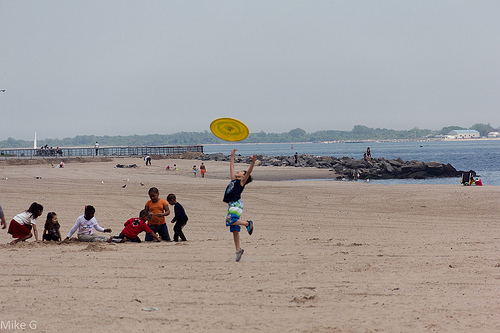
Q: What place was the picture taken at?
A: It was taken at the beach.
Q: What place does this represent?
A: It represents the beach.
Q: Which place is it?
A: It is a beach.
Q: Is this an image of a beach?
A: Yes, it is showing a beach.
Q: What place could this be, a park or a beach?
A: It is a beach.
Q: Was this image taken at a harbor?
A: No, the picture was taken in a beach.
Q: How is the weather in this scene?
A: It is overcast.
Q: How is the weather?
A: It is overcast.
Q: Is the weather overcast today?
A: Yes, it is overcast.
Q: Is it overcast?
A: Yes, it is overcast.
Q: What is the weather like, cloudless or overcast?
A: It is overcast.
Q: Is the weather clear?
A: No, it is overcast.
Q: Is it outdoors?
A: Yes, it is outdoors.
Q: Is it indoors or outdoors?
A: It is outdoors.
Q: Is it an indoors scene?
A: No, it is outdoors.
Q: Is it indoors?
A: No, it is outdoors.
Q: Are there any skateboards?
A: No, there are no skateboards.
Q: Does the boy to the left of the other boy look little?
A: Yes, the boy is little.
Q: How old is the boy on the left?
A: The boy is little.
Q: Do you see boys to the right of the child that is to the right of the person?
A: Yes, there is a boy to the right of the child.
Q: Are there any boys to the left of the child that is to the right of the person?
A: No, the boy is to the right of the child.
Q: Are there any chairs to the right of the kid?
A: No, there is a boy to the right of the kid.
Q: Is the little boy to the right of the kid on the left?
A: Yes, the boy is to the right of the kid.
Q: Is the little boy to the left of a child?
A: No, the boy is to the right of a child.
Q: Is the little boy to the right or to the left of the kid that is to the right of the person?
A: The boy is to the right of the kid.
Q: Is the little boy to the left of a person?
A: Yes, the boy is to the left of a person.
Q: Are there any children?
A: Yes, there is a child.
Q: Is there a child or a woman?
A: Yes, there is a child.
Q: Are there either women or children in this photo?
A: Yes, there is a child.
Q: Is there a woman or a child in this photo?
A: Yes, there is a child.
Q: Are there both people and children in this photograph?
A: Yes, there are both a child and a person.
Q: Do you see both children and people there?
A: Yes, there are both a child and a person.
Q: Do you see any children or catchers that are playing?
A: Yes, the child is playing.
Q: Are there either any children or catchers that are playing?
A: Yes, the child is playing.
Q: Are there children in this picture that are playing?
A: Yes, there is a child that is playing.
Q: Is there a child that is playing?
A: Yes, there is a child that is playing.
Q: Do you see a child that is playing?
A: Yes, there is a child that is playing.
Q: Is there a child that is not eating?
A: Yes, there is a child that is playing.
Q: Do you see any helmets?
A: No, there are no helmets.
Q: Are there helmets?
A: No, there are no helmets.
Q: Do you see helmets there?
A: No, there are no helmets.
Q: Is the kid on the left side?
A: Yes, the kid is on the left of the image.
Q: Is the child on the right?
A: No, the child is on the left of the image.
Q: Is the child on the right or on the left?
A: The child is on the left of the image.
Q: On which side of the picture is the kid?
A: The kid is on the left of the image.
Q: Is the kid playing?
A: Yes, the kid is playing.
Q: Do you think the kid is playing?
A: Yes, the kid is playing.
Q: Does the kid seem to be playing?
A: Yes, the kid is playing.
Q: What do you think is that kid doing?
A: The kid is playing.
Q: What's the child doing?
A: The kid is playing.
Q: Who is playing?
A: The child is playing.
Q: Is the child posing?
A: No, the child is playing.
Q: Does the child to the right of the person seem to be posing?
A: No, the child is playing.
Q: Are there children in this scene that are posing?
A: No, there is a child but he is playing.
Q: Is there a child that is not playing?
A: No, there is a child but he is playing.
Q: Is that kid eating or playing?
A: The kid is playing.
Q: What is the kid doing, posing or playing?
A: The kid is playing.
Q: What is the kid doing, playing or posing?
A: The kid is playing.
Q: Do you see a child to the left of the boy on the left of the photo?
A: Yes, there is a child to the left of the boy.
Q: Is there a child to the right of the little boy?
A: No, the child is to the left of the boy.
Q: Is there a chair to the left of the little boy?
A: No, there is a child to the left of the boy.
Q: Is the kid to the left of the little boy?
A: Yes, the kid is to the left of the boy.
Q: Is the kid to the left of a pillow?
A: No, the kid is to the left of the boy.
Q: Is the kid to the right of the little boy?
A: No, the kid is to the left of the boy.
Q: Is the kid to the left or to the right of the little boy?
A: The kid is to the left of the boy.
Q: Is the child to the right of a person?
A: No, the child is to the left of a person.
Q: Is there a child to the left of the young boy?
A: Yes, there is a child to the left of the boy.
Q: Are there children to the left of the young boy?
A: Yes, there is a child to the left of the boy.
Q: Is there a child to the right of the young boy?
A: No, the child is to the left of the boy.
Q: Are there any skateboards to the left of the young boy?
A: No, there is a child to the left of the boy.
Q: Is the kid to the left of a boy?
A: Yes, the kid is to the left of a boy.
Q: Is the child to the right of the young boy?
A: No, the child is to the left of the boy.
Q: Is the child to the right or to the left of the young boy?
A: The child is to the left of the boy.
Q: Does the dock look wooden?
A: Yes, the dock is wooden.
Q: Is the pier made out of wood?
A: Yes, the pier is made of wood.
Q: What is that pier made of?
A: The pier is made of wood.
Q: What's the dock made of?
A: The pier is made of wood.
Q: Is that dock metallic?
A: No, the dock is wooden.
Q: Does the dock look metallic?
A: No, the dock is wooden.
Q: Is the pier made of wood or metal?
A: The pier is made of wood.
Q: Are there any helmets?
A: No, there are no helmets.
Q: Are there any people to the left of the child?
A: Yes, there is a person to the left of the child.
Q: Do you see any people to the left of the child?
A: Yes, there is a person to the left of the child.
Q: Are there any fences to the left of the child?
A: No, there is a person to the left of the child.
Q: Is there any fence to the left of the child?
A: No, there is a person to the left of the child.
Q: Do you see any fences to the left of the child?
A: No, there is a person to the left of the child.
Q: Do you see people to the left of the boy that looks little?
A: Yes, there is a person to the left of the boy.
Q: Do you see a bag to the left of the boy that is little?
A: No, there is a person to the left of the boy.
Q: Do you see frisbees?
A: Yes, there is a frisbee.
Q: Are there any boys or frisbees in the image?
A: Yes, there is a frisbee.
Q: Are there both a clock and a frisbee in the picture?
A: No, there is a frisbee but no clocks.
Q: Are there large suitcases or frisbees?
A: Yes, there is a large frisbee.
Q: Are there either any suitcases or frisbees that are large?
A: Yes, the frisbee is large.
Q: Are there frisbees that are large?
A: Yes, there is a large frisbee.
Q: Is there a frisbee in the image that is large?
A: Yes, there is a frisbee that is large.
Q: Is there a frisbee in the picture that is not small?
A: Yes, there is a large frisbee.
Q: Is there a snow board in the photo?
A: No, there are no snowboards.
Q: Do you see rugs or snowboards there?
A: No, there are no snowboards or rugs.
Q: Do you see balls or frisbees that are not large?
A: No, there is a frisbee but it is large.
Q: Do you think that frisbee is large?
A: Yes, the frisbee is large.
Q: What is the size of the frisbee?
A: The frisbee is large.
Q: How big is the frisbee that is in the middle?
A: The frisbee is large.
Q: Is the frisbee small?
A: No, the frisbee is large.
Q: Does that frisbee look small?
A: No, the frisbee is large.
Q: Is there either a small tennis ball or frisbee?
A: No, there is a frisbee but it is large.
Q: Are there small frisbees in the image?
A: No, there is a frisbee but it is large.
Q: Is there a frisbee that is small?
A: No, there is a frisbee but it is large.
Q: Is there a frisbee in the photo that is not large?
A: No, there is a frisbee but it is large.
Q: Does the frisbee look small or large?
A: The frisbee is large.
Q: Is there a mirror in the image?
A: No, there are no mirrors.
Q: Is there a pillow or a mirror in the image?
A: No, there are no mirrors or pillows.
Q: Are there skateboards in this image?
A: No, there are no skateboards.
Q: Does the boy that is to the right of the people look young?
A: Yes, the boy is young.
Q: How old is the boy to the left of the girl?
A: The boy is young.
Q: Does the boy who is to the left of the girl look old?
A: No, the boy is young.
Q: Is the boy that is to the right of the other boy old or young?
A: The boy is young.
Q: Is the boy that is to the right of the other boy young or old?
A: The boy is young.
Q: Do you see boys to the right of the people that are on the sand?
A: Yes, there is a boy to the right of the people.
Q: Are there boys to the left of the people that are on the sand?
A: No, the boy is to the right of the people.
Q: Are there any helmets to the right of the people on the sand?
A: No, there is a boy to the right of the people.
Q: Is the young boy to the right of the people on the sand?
A: Yes, the boy is to the right of the people.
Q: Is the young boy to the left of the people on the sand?
A: No, the boy is to the right of the people.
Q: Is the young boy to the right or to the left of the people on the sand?
A: The boy is to the right of the people.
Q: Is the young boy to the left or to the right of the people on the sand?
A: The boy is to the right of the people.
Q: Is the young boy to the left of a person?
A: Yes, the boy is to the left of a person.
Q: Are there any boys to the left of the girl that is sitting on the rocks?
A: Yes, there is a boy to the left of the girl.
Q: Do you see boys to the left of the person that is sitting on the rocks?
A: Yes, there is a boy to the left of the girl.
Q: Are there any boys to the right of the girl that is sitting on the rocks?
A: No, the boy is to the left of the girl.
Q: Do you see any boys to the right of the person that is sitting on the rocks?
A: No, the boy is to the left of the girl.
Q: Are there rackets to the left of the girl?
A: No, there is a boy to the left of the girl.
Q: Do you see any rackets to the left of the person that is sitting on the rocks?
A: No, there is a boy to the left of the girl.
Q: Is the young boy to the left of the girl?
A: Yes, the boy is to the left of the girl.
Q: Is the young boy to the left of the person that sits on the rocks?
A: Yes, the boy is to the left of the girl.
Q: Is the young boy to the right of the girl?
A: No, the boy is to the left of the girl.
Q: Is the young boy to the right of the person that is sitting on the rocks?
A: No, the boy is to the left of the girl.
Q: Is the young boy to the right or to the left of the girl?
A: The boy is to the left of the girl.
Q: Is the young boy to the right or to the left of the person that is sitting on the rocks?
A: The boy is to the left of the girl.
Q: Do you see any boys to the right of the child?
A: Yes, there is a boy to the right of the child.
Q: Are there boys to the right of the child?
A: Yes, there is a boy to the right of the child.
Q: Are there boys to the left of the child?
A: No, the boy is to the right of the child.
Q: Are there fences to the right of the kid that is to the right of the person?
A: No, there is a boy to the right of the kid.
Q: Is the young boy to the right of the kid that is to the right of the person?
A: Yes, the boy is to the right of the child.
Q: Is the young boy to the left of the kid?
A: No, the boy is to the right of the kid.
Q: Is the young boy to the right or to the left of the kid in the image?
A: The boy is to the right of the kid.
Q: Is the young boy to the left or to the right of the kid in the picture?
A: The boy is to the right of the kid.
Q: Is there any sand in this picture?
A: Yes, there is sand.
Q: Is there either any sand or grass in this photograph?
A: Yes, there is sand.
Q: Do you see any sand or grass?
A: Yes, there is sand.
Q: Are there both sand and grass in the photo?
A: No, there is sand but no grass.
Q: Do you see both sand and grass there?
A: No, there is sand but no grass.